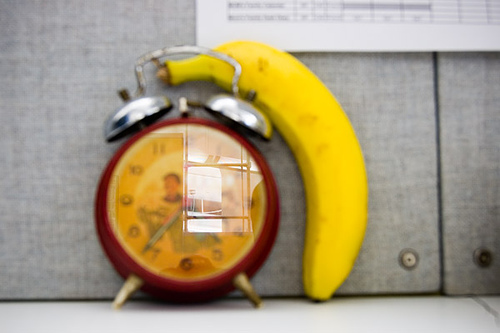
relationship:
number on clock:
[210, 132, 224, 156] [88, 35, 285, 313]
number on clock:
[173, 257, 197, 277] [88, 35, 285, 313]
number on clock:
[208, 249, 225, 263] [104, 121, 266, 283]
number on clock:
[121, 222, 144, 241] [84, 80, 249, 270]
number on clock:
[116, 195, 141, 210] [73, 37, 293, 302]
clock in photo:
[88, 35, 285, 313] [60, 77, 483, 293]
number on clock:
[180, 257, 195, 270] [71, 95, 309, 287]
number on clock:
[241, 192, 261, 217] [75, 55, 305, 313]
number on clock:
[116, 193, 135, 208] [82, 140, 237, 239]